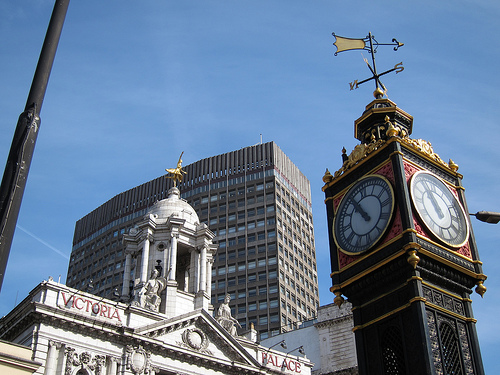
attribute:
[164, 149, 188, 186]
scultpure — golden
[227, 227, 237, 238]
window — clear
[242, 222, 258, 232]
window — clear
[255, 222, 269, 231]
window — clear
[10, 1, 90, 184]
pole — black , Tall , metal 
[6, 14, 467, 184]
sky — blue 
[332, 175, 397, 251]
clock — black, white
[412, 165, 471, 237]
clock — black, white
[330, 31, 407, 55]
arrow — metal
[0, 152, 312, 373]
palace — victoria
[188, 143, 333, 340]
building — Tall , grayish , modern 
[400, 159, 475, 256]
clock — white, black 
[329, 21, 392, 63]
yellow vane — yellow 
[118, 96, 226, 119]
clouds — white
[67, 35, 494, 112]
sky — blue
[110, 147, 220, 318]
structure — architectural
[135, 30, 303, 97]
sky — blue 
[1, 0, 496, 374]
sky — blue 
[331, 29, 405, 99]
spinning piece — metal 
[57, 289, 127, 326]
lettering — red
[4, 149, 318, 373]
building — White 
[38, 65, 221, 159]
clouds — white 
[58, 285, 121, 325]
letters — red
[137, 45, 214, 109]
clouds — white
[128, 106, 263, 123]
sky — blue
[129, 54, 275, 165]
clouds — white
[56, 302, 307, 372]
building — white